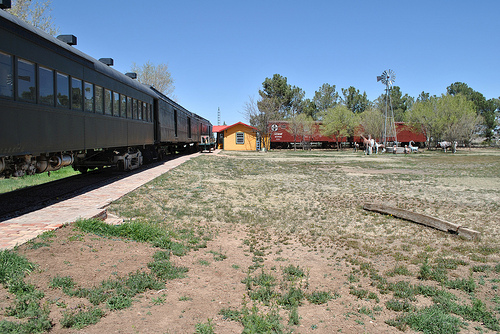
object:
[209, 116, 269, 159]
building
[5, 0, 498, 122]
sky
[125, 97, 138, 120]
window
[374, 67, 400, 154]
weather vane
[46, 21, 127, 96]
boxes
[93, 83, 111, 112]
window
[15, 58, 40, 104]
window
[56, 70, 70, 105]
window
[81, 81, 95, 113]
window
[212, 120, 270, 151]
house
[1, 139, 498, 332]
sand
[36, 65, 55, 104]
window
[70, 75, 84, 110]
window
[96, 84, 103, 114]
window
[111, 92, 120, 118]
window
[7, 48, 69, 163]
window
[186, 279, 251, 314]
ground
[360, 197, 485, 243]
object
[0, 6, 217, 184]
train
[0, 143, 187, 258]
track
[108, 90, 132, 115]
glass window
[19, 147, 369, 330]
ground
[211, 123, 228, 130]
red roof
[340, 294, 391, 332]
pebbles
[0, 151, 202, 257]
path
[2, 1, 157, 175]
car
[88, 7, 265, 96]
clouds